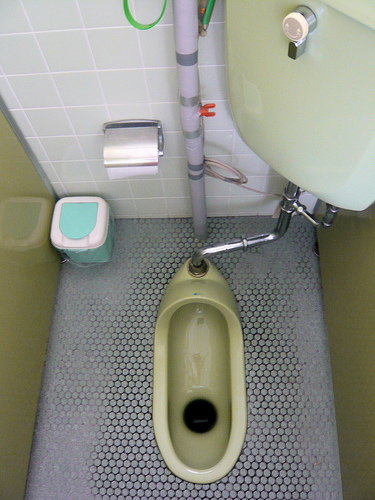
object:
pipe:
[170, 0, 209, 240]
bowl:
[152, 256, 246, 485]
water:
[184, 304, 212, 389]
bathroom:
[0, 0, 375, 500]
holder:
[101, 116, 164, 183]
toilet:
[223, 0, 374, 213]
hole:
[181, 396, 217, 433]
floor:
[31, 215, 340, 498]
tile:
[20, 3, 87, 37]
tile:
[84, 25, 143, 75]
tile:
[51, 158, 95, 188]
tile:
[26, 106, 79, 141]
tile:
[96, 64, 154, 110]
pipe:
[192, 180, 300, 268]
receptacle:
[49, 195, 116, 264]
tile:
[124, 177, 170, 203]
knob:
[198, 104, 216, 118]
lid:
[50, 196, 110, 250]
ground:
[24, 213, 344, 500]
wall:
[0, 2, 318, 216]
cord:
[203, 158, 285, 198]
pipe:
[187, 181, 338, 273]